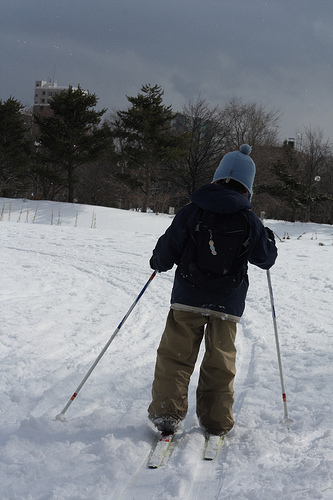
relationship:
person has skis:
[155, 129, 300, 479] [141, 394, 262, 492]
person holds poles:
[155, 129, 300, 479] [59, 224, 283, 415]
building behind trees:
[54, 69, 307, 218] [17, 92, 320, 230]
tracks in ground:
[61, 254, 149, 317] [8, 245, 118, 500]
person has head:
[155, 129, 300, 479] [193, 153, 275, 224]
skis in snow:
[141, 394, 262, 492] [20, 423, 331, 487]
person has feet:
[155, 129, 300, 479] [143, 419, 252, 451]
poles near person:
[59, 224, 283, 415] [155, 129, 300, 479]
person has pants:
[155, 129, 300, 479] [172, 301, 228, 425]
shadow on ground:
[23, 399, 154, 451] [8, 245, 118, 500]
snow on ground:
[20, 423, 331, 487] [8, 245, 118, 500]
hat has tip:
[220, 147, 261, 187] [246, 141, 249, 155]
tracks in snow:
[61, 254, 149, 317] [20, 423, 331, 487]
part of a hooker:
[276, 360, 284, 375] [198, 210, 250, 268]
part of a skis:
[211, 438, 223, 450] [141, 394, 262, 492]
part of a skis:
[158, 437, 170, 449] [141, 394, 262, 492]